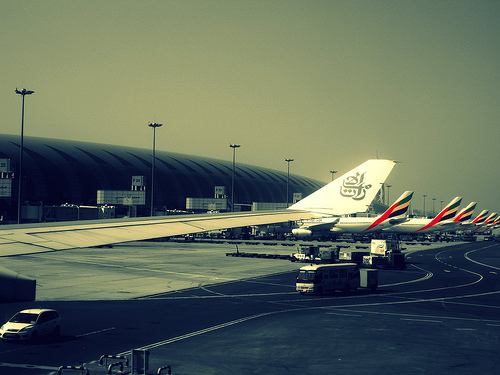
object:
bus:
[291, 260, 366, 300]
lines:
[426, 249, 500, 310]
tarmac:
[398, 238, 500, 372]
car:
[3, 306, 69, 341]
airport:
[4, 124, 320, 222]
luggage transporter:
[288, 238, 386, 266]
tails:
[380, 190, 499, 242]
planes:
[283, 185, 498, 239]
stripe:
[424, 197, 459, 230]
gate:
[98, 176, 149, 209]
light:
[15, 79, 35, 107]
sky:
[8, 12, 478, 124]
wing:
[7, 198, 319, 256]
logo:
[336, 171, 373, 201]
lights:
[13, 88, 338, 177]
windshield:
[11, 311, 41, 326]